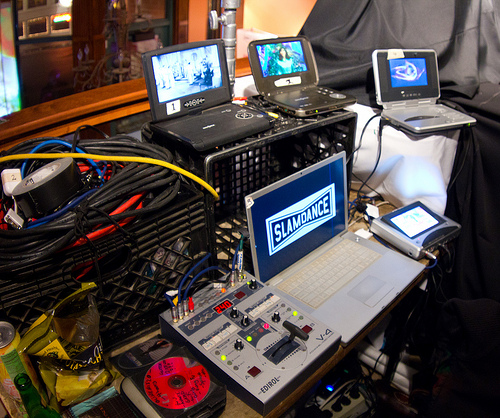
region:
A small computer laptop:
[372, 39, 473, 130]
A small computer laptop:
[252, 27, 343, 108]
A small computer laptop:
[137, 41, 262, 141]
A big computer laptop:
[238, 202, 428, 333]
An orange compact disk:
[145, 359, 210, 401]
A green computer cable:
[167, 254, 214, 294]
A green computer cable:
[44, 184, 90, 228]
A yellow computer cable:
[102, 148, 214, 208]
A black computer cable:
[33, 184, 147, 249]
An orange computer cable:
[99, 191, 134, 242]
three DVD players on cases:
[126, 29, 486, 205]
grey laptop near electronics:
[215, 176, 410, 356]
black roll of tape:
[13, 151, 95, 228]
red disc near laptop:
[120, 363, 211, 398]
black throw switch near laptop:
[257, 323, 307, 369]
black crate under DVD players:
[181, 99, 359, 219]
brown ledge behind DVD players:
[0, 68, 135, 162]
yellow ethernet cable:
[36, 144, 253, 223]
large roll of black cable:
[43, 134, 158, 236]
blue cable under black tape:
[24, 129, 111, 249]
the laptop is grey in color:
[236, 160, 428, 347]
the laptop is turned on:
[249, 144, 351, 267]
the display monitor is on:
[247, 158, 357, 286]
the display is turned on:
[376, 49, 444, 103]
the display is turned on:
[255, 34, 319, 84]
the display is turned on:
[153, 35, 230, 97]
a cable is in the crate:
[6, 138, 222, 207]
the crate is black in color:
[0, 180, 230, 353]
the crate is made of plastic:
[0, 135, 220, 331]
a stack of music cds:
[105, 331, 237, 417]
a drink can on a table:
[0, 316, 50, 405]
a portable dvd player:
[370, 46, 477, 139]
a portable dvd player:
[129, 40, 273, 155]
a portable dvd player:
[240, 35, 360, 120]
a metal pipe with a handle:
[208, 2, 240, 97]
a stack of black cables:
[5, 125, 188, 285]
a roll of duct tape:
[13, 154, 87, 221]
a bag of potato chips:
[18, 282, 121, 404]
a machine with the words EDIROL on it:
[148, 261, 353, 415]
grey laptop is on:
[245, 154, 397, 323]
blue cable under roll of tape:
[10, 115, 111, 262]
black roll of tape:
[5, 156, 93, 221]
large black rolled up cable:
[10, 114, 181, 269]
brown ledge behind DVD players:
[18, 70, 138, 157]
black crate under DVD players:
[194, 76, 383, 235]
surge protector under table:
[305, 382, 360, 415]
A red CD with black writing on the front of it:
[138, 353, 213, 410]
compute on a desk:
[219, 145, 428, 347]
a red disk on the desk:
[139, 352, 216, 410]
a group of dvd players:
[132, 22, 470, 166]